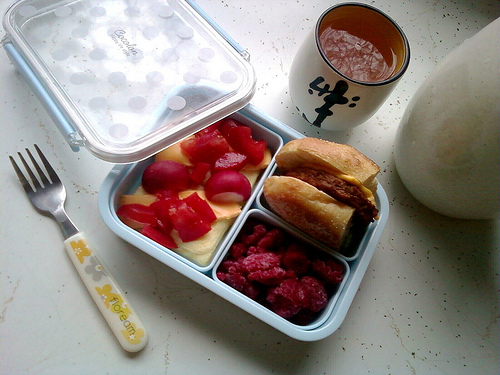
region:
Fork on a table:
[3, 141, 159, 373]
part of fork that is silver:
[3, 132, 75, 234]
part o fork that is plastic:
[63, 231, 155, 355]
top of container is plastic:
[0, 0, 264, 171]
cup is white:
[281, 1, 416, 139]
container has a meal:
[101, 65, 396, 347]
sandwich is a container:
[262, 126, 394, 246]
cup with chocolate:
[276, 1, 420, 142]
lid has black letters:
[96, 13, 148, 67]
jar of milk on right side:
[396, 8, 497, 243]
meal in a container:
[97, 77, 397, 337]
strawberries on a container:
[217, 217, 354, 321]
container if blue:
[99, 85, 399, 342]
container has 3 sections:
[87, 73, 398, 348]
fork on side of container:
[7, 134, 155, 361]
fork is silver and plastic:
[10, 136, 167, 365]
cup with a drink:
[276, 0, 417, 133]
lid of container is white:
[3, 0, 258, 171]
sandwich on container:
[256, 125, 388, 247]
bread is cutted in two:
[254, 127, 391, 254]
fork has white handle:
[6, 140, 131, 362]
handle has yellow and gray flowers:
[63, 257, 185, 344]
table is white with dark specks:
[416, 259, 498, 336]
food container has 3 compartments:
[178, 84, 405, 341]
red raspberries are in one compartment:
[261, 232, 348, 317]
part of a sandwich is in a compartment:
[298, 144, 383, 234]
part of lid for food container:
[31, 79, 241, 161]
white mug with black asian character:
[298, 6, 438, 123]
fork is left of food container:
[16, 148, 181, 373]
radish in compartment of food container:
[203, 160, 260, 210]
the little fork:
[10, 140, 147, 355]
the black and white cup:
[295, 7, 407, 130]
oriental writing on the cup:
[301, 73, 356, 129]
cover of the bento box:
[4, 4, 261, 153]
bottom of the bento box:
[104, 83, 391, 347]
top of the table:
[382, 272, 462, 368]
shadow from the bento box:
[113, 240, 303, 365]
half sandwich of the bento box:
[279, 140, 371, 236]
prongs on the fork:
[11, 147, 70, 207]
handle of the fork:
[66, 229, 148, 350]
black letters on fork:
[85, 279, 167, 362]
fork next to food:
[6, 130, 151, 373]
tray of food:
[85, 77, 397, 338]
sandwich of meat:
[263, 124, 402, 248]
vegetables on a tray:
[122, 97, 267, 255]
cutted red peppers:
[117, 185, 224, 254]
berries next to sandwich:
[213, 211, 361, 340]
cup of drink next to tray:
[276, 1, 426, 139]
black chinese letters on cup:
[283, 71, 370, 137]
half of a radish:
[197, 159, 258, 209]